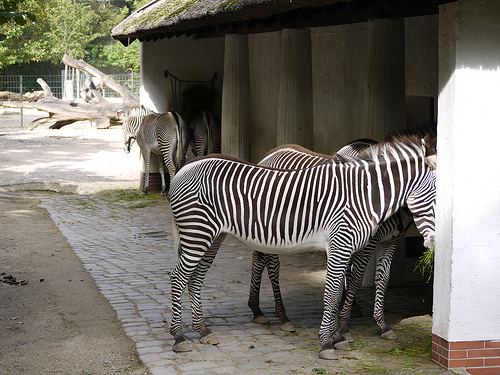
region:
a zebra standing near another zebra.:
[152, 134, 449, 369]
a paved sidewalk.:
[23, 128, 443, 373]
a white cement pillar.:
[415, 0, 497, 370]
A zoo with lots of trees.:
[0, 0, 145, 222]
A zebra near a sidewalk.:
[105, 97, 200, 188]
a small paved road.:
[0, 190, 150, 371]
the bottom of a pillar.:
[432, 327, 497, 372]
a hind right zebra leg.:
[163, 231, 219, 351]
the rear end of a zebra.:
[157, 145, 230, 276]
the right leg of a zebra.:
[299, 243, 369, 345]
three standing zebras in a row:
[168, 135, 435, 353]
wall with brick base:
[432, 18, 497, 367]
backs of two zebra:
[122, 107, 217, 188]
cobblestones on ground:
[51, 191, 402, 373]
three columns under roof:
[122, 0, 441, 153]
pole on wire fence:
[2, 72, 139, 129]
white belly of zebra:
[215, 231, 332, 252]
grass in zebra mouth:
[410, 193, 435, 279]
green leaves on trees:
[4, 3, 118, 70]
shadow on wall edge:
[436, 1, 498, 159]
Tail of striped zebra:
[173, 117, 185, 163]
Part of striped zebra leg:
[172, 211, 184, 333]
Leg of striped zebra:
[320, 242, 345, 362]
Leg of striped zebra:
[368, 240, 395, 346]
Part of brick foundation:
[455, 347, 496, 370]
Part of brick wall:
[450, 128, 483, 248]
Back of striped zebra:
[228, 171, 325, 204]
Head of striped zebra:
[120, 117, 133, 157]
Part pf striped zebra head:
[403, 148, 436, 251]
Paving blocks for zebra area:
[84, 212, 146, 273]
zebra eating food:
[170, 137, 435, 357]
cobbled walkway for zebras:
[40, 190, 440, 372]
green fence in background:
[0, 71, 141, 126]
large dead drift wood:
[28, 52, 137, 129]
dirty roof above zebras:
[110, 2, 498, 47]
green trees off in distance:
[1, 0, 153, 95]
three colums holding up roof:
[221, 14, 405, 157]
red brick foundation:
[431, 332, 498, 372]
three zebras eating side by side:
[168, 137, 437, 358]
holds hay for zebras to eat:
[163, 69, 221, 117]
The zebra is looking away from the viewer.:
[121, 103, 193, 194]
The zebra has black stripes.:
[166, 135, 438, 362]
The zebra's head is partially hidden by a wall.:
[169, 137, 437, 360]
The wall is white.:
[430, 0, 499, 340]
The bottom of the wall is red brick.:
[429, 328, 498, 373]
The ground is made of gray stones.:
[37, 188, 452, 374]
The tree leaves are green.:
[0, 0, 142, 65]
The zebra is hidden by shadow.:
[184, 100, 221, 161]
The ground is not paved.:
[0, 110, 152, 374]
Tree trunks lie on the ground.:
[0, 55, 139, 132]